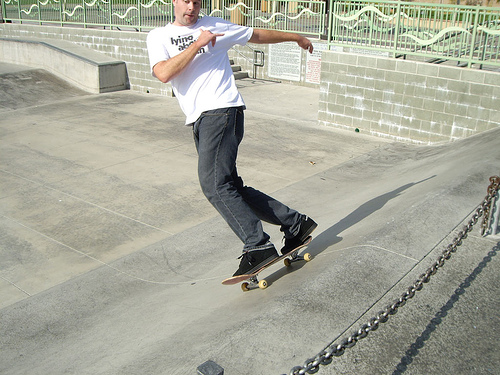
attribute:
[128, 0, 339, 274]
man — skating, skateboarding, standing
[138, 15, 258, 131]
shirt — white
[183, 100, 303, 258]
pants — grey, blue, green, jeans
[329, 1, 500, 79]
rail — green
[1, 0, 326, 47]
rail — green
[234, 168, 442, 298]
shadow — falling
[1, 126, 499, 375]
ground — concrete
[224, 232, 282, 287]
shoe — black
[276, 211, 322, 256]
shoe — black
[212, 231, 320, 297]
skateboard — black, dark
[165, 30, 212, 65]
letters — black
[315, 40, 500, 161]
wall — gray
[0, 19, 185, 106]
wall — gray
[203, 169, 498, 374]
chain — silver